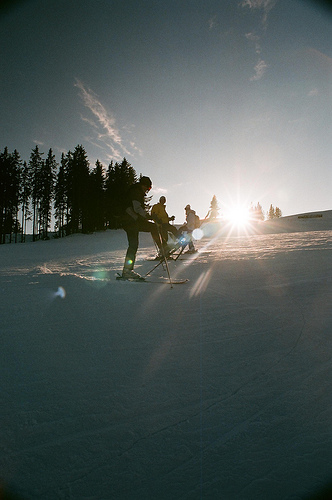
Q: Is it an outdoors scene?
A: Yes, it is outdoors.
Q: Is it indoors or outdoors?
A: It is outdoors.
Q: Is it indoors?
A: No, it is outdoors.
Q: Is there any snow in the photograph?
A: Yes, there is snow.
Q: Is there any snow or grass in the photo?
A: Yes, there is snow.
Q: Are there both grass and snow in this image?
A: No, there is snow but no grass.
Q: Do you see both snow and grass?
A: No, there is snow but no grass.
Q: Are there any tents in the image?
A: No, there are no tents.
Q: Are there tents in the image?
A: No, there are no tents.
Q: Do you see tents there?
A: No, there are no tents.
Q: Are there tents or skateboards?
A: No, there are no tents or skateboards.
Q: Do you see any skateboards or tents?
A: No, there are no tents or skateboards.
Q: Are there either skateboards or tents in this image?
A: No, there are no tents or skateboards.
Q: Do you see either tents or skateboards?
A: No, there are no tents or skateboards.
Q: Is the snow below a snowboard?
A: No, the snow is below a ski.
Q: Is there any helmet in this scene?
A: No, there are no helmets.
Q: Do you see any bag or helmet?
A: No, there are no helmets or bags.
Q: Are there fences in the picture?
A: No, there are no fences.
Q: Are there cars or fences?
A: No, there are no fences or cars.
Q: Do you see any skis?
A: Yes, there are skis.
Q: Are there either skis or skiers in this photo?
A: Yes, there are skis.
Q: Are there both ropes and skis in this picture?
A: No, there are skis but no ropes.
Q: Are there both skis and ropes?
A: No, there are skis but no ropes.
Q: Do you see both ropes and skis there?
A: No, there are skis but no ropes.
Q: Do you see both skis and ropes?
A: No, there are skis but no ropes.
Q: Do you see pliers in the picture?
A: No, there are no pliers.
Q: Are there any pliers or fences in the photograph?
A: No, there are no pliers or fences.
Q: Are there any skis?
A: Yes, there are skis.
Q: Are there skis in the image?
A: Yes, there are skis.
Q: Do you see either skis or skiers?
A: Yes, there are skis.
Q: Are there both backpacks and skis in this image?
A: No, there are skis but no backpacks.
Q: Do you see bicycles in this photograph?
A: No, there are no bicycles.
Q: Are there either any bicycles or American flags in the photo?
A: No, there are no bicycles or American flags.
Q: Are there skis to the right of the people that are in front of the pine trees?
A: Yes, there are skis to the right of the people.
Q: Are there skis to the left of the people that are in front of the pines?
A: No, the skis are to the right of the people.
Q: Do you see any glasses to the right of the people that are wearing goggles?
A: No, there are skis to the right of the people.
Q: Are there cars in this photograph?
A: No, there are no cars.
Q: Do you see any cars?
A: No, there are no cars.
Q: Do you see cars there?
A: No, there are no cars.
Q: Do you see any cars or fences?
A: No, there are no cars or fences.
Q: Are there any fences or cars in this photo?
A: No, there are no cars or fences.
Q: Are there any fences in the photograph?
A: No, there are no fences.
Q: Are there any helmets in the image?
A: No, there are no helmets.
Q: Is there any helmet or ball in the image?
A: No, there are no helmets or balls.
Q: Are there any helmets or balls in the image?
A: No, there are no helmets or balls.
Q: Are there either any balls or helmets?
A: No, there are no helmets or balls.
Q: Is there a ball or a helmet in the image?
A: No, there are no helmets or balls.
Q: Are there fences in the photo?
A: No, there are no fences.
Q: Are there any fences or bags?
A: No, there are no fences or bags.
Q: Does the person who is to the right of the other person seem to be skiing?
A: Yes, the person is skiing.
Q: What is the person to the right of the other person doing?
A: The person is skiing.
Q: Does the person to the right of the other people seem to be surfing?
A: No, the person is skiing.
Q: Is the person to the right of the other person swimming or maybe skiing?
A: The person is skiing.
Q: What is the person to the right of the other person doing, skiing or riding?
A: The person is skiing.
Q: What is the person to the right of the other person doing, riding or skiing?
A: The person is skiing.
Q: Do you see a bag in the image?
A: No, there are no bags.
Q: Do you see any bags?
A: No, there are no bags.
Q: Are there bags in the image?
A: No, there are no bags.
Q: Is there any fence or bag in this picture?
A: No, there are no bags or fences.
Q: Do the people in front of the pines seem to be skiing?
A: Yes, the people are skiing.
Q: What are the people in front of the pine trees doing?
A: The people are skiing.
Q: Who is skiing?
A: The people are skiing.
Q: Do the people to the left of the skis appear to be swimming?
A: No, the people are skiing.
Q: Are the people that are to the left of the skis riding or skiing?
A: The people are skiing.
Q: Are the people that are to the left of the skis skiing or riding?
A: The people are skiing.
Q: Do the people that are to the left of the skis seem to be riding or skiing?
A: The people are skiing.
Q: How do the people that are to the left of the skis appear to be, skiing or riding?
A: The people are skiing.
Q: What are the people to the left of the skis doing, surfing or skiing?
A: The people are skiing.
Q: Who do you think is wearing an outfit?
A: The people are wearing an outfit.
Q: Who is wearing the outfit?
A: The people are wearing an outfit.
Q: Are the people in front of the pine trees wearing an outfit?
A: Yes, the people are wearing an outfit.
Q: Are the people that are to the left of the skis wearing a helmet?
A: No, the people are wearing an outfit.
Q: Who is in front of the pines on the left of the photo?
A: The people are in front of the pine trees.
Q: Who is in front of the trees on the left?
A: The people are in front of the pine trees.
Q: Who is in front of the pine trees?
A: The people are in front of the pine trees.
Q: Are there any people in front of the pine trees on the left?
A: Yes, there are people in front of the pine trees.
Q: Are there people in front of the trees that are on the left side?
A: Yes, there are people in front of the pine trees.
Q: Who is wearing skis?
A: The people are wearing skis.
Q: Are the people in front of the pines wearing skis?
A: Yes, the people are wearing skis.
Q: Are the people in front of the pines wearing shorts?
A: No, the people are wearing skis.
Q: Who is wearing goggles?
A: The people are wearing goggles.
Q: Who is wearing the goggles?
A: The people are wearing goggles.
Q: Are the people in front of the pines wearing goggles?
A: Yes, the people are wearing goggles.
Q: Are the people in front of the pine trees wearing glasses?
A: No, the people are wearing goggles.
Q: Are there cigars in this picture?
A: No, there are no cigars.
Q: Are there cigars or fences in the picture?
A: No, there are no cigars or fences.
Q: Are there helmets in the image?
A: No, there are no helmets.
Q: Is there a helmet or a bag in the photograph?
A: No, there are no helmets or bags.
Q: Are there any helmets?
A: No, there are no helmets.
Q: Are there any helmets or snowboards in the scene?
A: No, there are no helmets or snowboards.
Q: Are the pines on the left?
A: Yes, the pines are on the left of the image.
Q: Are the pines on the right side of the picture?
A: No, the pines are on the left of the image.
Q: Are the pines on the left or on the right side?
A: The pines are on the left of the image.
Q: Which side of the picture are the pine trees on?
A: The pine trees are on the left of the image.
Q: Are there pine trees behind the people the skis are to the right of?
A: Yes, there are pine trees behind the people.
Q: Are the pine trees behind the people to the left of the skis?
A: Yes, the pine trees are behind the people.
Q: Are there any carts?
A: No, there are no carts.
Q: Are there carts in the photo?
A: No, there are no carts.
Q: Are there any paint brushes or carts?
A: No, there are no carts or paint brushes.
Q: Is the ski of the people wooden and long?
A: Yes, the ski is wooden and long.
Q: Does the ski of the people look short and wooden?
A: No, the ski is wooden but long.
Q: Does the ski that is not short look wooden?
A: Yes, the ski is wooden.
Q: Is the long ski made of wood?
A: Yes, the ski is made of wood.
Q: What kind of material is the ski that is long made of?
A: The ski is made of wood.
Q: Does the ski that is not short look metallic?
A: No, the ski is wooden.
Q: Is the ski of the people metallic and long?
A: No, the ski is long but wooden.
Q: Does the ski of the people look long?
A: Yes, the ski is long.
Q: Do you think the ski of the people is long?
A: Yes, the ski is long.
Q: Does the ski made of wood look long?
A: Yes, the ski is long.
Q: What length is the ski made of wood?
A: The ski is long.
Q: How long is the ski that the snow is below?
A: The ski is long.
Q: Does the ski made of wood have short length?
A: No, the ski is long.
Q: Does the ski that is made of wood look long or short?
A: The ski is long.